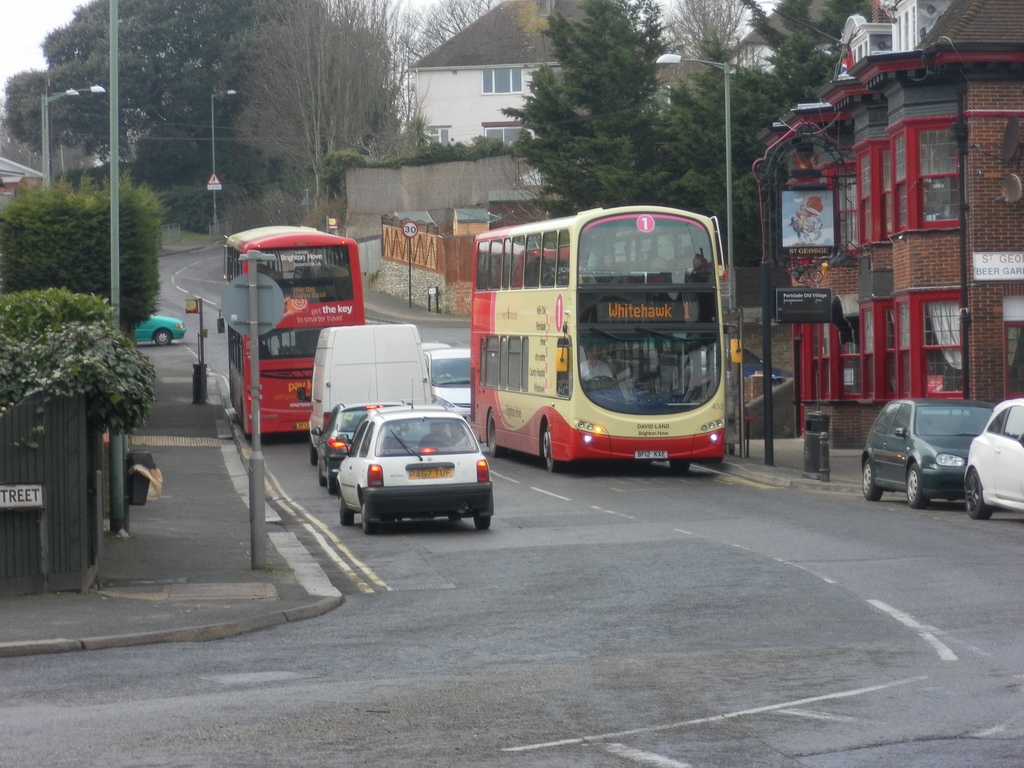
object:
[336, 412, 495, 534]
dcompactcar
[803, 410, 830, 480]
trashbin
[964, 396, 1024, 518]
car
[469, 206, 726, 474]
bus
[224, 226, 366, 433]
redbus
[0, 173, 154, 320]
bush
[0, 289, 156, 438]
bush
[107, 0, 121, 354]
streetlight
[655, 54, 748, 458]
streetlight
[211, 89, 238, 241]
streetlight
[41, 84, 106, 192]
streetlight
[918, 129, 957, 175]
window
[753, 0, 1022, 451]
building.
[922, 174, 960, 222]
window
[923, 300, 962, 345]
window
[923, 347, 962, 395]
window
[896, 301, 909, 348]
window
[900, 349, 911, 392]
window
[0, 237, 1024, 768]
road